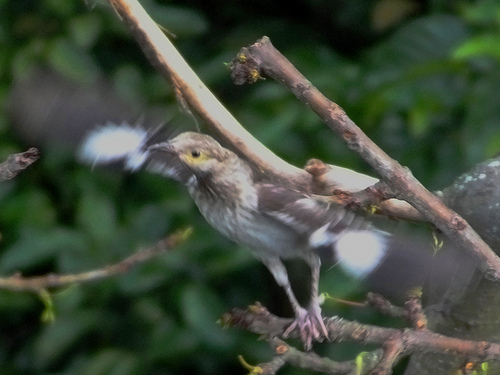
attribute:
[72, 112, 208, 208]
wing — gray, white, moving, blurry, grey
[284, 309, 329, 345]
feet — skinny, long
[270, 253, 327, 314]
legs — thin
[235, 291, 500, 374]
branch — long, thin, here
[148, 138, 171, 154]
beak — sharp, black, grey, long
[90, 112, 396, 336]
bird — gray, white, brown, feathered, here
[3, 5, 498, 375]
vegetation — green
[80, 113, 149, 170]
spot — white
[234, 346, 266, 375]
blossom — green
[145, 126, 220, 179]
head — small, gray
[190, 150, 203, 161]
eye — black, round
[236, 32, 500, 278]
branch — large, brown, broken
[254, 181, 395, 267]
wing — gray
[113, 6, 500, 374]
branches — dry